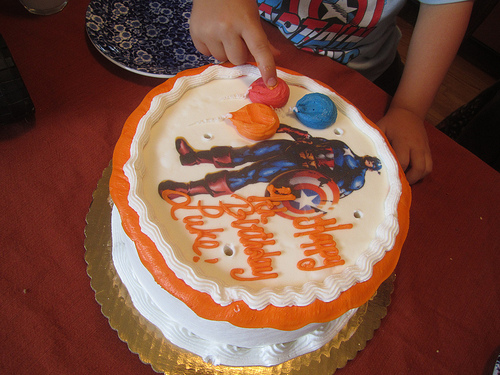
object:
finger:
[241, 31, 279, 86]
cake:
[105, 63, 414, 368]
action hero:
[157, 121, 384, 219]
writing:
[157, 181, 355, 283]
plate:
[82, 0, 229, 79]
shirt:
[256, 0, 480, 84]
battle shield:
[263, 168, 344, 221]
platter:
[82, 160, 404, 375]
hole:
[223, 246, 234, 257]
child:
[188, 0, 476, 185]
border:
[110, 62, 412, 331]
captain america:
[252, 0, 387, 69]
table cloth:
[1, 0, 498, 372]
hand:
[378, 108, 437, 187]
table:
[3, 0, 499, 374]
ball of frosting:
[228, 103, 280, 141]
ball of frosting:
[290, 90, 341, 130]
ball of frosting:
[248, 76, 292, 108]